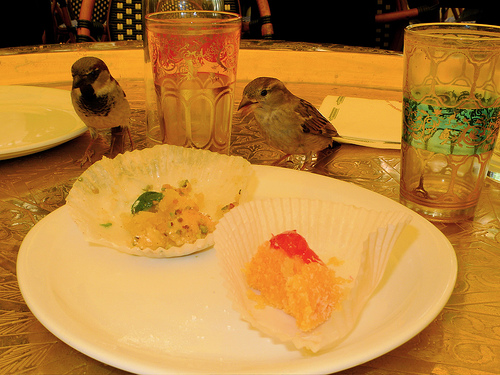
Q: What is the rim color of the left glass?
A: Red.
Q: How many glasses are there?
A: Two.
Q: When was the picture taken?
A: Lunch.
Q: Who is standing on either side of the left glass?
A: Birds.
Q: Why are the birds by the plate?
A: Hungry.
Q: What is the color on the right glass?
A: Green.